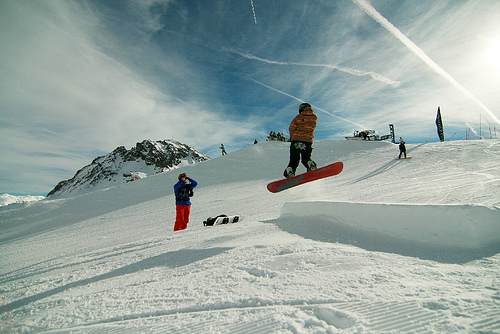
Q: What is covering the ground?
A: Snow.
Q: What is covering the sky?
A: Clouds.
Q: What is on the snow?
A: Track marks.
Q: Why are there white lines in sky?
A: They are from airplanes.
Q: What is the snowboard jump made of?
A: Snow.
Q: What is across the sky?
A: White streaks.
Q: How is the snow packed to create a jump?
A: It is packed tightly.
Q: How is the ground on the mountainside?
A: Covered with snow.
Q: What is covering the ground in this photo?
A: Snow.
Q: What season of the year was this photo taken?
A: Winter.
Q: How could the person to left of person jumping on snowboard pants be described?
A: Red.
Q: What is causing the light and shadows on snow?
A: Sun.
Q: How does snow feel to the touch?
A: Cold.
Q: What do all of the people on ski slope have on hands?
A: Gloves.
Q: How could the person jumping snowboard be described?
A: Red.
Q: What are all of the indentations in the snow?
A: Foot and snowboard prints.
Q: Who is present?
A: No one.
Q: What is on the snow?
A: Tracks.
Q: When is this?
A: Daytime.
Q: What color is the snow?
A: White.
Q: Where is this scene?
A: Mountain.